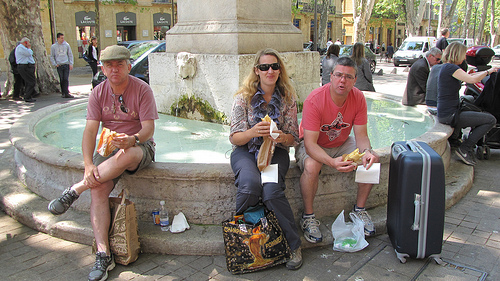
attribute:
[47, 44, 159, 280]
man — sitting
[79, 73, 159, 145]
shirt — pinkish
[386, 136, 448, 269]
suitcase — black, large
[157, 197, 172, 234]
bottle — clear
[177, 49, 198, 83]
lion head — white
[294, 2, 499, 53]
trees — grouped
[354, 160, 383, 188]
napkin — white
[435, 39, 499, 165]
woman — blonde, resting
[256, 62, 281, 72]
sunglasses — dark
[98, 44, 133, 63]
cap — brown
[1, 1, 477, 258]
fountain — large, concrete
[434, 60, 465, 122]
shirt — black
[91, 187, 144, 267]
bag — brown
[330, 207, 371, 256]
bag — white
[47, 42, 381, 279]
people — eating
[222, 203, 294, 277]
bag — decorative, black, yellow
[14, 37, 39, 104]
man — overweight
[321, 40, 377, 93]
two women — sitting